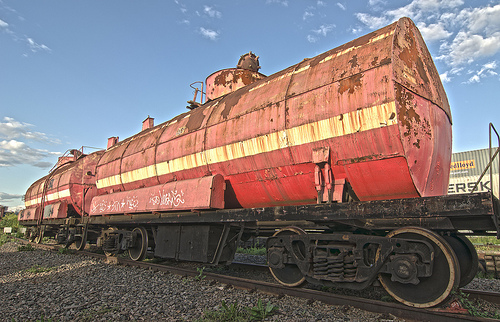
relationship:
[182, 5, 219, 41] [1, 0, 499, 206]
cloud in sky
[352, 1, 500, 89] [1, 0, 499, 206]
cloud in sky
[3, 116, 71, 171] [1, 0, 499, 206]
cloud in sky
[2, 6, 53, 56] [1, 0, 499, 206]
cloud in sky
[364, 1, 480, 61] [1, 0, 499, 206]
cloud in sky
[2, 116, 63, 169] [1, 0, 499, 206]
clouds in sky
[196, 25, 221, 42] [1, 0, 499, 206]
cloud in sky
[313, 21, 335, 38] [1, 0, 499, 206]
cloud in sky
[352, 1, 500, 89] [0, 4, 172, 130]
cloud in blue sky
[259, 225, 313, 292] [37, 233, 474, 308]
car wheel on track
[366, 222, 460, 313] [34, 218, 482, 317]
wheels on track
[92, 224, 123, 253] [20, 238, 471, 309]
wheel on track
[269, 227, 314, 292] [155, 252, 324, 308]
car wheel on track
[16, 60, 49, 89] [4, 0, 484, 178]
clouds in sky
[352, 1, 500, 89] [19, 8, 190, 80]
cloud in blue sky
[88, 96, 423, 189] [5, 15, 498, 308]
stripes on car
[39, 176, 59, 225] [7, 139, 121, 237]
ladder on side of car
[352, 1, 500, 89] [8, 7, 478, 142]
cloud in sky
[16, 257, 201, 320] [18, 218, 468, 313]
gravel on side of track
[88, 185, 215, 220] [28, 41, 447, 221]
graffitti on side of car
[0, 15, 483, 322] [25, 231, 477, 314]
train on track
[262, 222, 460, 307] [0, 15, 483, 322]
wheels of train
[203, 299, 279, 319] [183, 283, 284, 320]
grass growing in gravel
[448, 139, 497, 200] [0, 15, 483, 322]
building behind train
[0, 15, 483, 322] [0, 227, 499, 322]
train on train tracks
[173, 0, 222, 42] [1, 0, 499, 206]
clouds in sky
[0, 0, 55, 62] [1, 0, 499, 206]
clouds in sky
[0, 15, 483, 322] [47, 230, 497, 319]
train drives on tracks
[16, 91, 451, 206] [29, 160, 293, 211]
train carrying carts